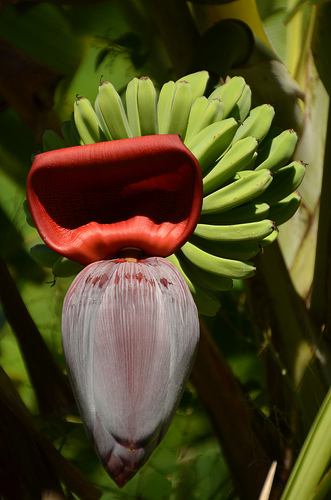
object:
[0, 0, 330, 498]
tree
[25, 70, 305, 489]
fruit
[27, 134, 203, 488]
red color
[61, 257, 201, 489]
bottom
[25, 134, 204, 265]
top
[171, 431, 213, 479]
leaves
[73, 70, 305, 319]
banana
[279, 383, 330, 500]
stem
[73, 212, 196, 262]
out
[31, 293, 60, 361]
back